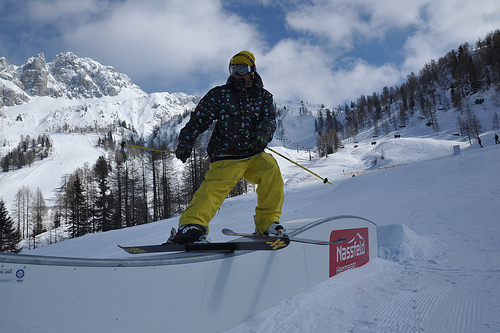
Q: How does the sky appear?
A: Blue with white clouds.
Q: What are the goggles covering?
A: Skier's eyes.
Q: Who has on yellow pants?
A: Man skiing.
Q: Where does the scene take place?
A: On a ski slope.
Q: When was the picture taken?
A: During daytime.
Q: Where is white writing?
A: On red sign.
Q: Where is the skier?
A: On a ski slope.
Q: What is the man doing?
A: Skiing.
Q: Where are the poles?
A: In the man's hands.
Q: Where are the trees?
A: On the slope.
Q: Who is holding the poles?
A: The skier.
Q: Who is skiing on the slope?
A: The man.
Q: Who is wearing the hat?
A: The skier.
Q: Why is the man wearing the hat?
A: Warmth.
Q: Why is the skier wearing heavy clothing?
A: To keep warm.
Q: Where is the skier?
A: On the ramp.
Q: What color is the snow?
A: White.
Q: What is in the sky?
A: Clouds.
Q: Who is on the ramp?
A: The skier.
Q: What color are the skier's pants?
A: Yellow.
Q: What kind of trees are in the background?
A: Pine.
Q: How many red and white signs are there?
A: One.